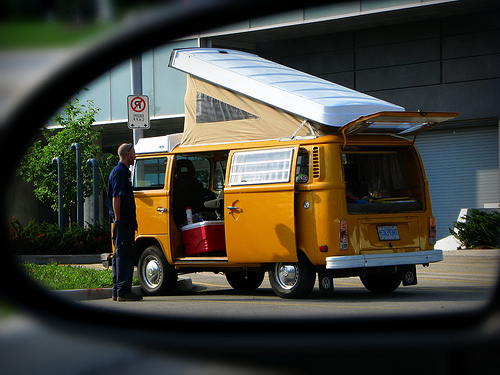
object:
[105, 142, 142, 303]
man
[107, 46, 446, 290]
van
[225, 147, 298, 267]
door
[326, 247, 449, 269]
bumper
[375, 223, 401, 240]
plate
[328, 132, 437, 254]
back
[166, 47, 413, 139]
popup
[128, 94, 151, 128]
sign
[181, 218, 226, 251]
cooler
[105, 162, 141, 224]
shirt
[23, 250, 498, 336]
lot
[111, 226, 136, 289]
jeans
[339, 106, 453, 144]
window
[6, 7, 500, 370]
mirror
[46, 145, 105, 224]
pipes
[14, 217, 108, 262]
plantings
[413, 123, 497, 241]
gate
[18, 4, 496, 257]
building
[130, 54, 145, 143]
pole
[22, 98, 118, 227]
tree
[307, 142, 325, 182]
vents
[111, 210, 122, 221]
hand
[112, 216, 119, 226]
pocket